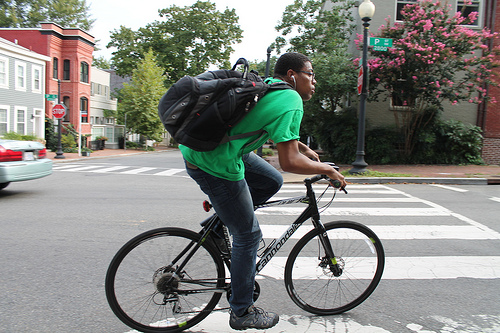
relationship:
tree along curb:
[115, 46, 175, 147] [46, 147, 167, 161]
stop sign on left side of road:
[47, 87, 74, 121] [125, 166, 471, 318]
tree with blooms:
[369, 3, 490, 173] [355, 0, 491, 99]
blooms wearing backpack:
[388, 59, 395, 65] [156, 58, 294, 152]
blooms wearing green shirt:
[388, 59, 395, 65] [175, 76, 308, 181]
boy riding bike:
[179, 49, 346, 330] [74, 168, 401, 330]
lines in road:
[360, 179, 469, 278] [0, 146, 500, 333]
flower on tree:
[457, 11, 463, 20] [433, 41, 446, 49]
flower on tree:
[347, 29, 364, 50] [433, 41, 446, 49]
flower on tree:
[464, 4, 481, 24] [433, 41, 446, 49]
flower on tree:
[416, 11, 428, 26] [433, 41, 446, 49]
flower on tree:
[402, 38, 414, 48] [433, 41, 446, 49]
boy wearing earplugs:
[179, 49, 346, 330] [286, 73, 296, 90]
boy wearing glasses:
[179, 49, 346, 330] [296, 69, 320, 80]